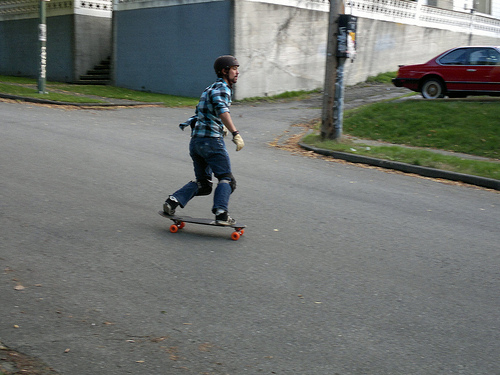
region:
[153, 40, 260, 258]
a man skateboarding down a street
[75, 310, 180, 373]
debris on a paved road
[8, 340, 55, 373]
cracks in a paved road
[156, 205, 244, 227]
a black skateboard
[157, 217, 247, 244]
red wheels on a black skateboard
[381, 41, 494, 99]
the side of a red compact car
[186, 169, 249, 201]
black kneepads on a man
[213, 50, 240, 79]
a black helmet on a man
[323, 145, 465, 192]
a gray concrete curb by the street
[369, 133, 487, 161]
a gray concrete sidewalk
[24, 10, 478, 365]
This is a skateboarding scene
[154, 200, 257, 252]
This is a skateboard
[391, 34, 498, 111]
A car is parked here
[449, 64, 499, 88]
The car is red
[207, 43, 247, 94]
The man is wearing a helmet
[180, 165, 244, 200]
Knee pads are being worn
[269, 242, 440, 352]
The street surface is asphalt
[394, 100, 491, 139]
A grassy area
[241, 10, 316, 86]
A concrete wall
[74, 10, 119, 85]
A set of stairs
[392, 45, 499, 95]
part of a red car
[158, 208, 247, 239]
a red and black skateboard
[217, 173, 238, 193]
a black knee pad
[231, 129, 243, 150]
a brown glove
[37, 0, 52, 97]
a tall pole with white writing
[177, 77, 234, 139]
a man's blue checkered shirt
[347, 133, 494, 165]
a concrete walkway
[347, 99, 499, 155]
a section of green grass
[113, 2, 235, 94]
part of a concrete wall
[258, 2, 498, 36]
a long white rail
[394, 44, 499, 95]
red car in parking lot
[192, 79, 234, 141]
blue and white plaid shirt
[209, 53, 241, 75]
black skate board helmet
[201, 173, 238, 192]
pair of black knee pads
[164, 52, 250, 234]
man skateboarding on street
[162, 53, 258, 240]
man standing on skateboard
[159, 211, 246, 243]
black skateboard with orange wheels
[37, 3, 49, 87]
grey metal light pole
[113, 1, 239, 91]
grey and white concrete wall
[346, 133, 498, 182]
grey cement side walk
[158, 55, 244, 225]
guy riding skateboard in street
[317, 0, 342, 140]
tall wooden telephone pole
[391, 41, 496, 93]
red sedan car parked near grass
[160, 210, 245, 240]
black skateboard under guy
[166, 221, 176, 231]
red wheel on skateboard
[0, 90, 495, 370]
black asphalt paved street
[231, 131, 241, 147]
white glove on man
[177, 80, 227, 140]
plaid shirt on man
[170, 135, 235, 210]
dark blue jeans on man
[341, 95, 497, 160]
green grass next to car